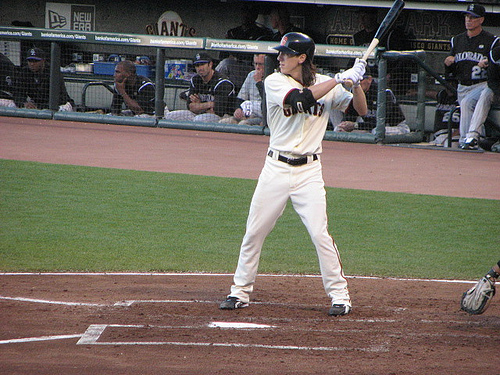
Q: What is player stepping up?
A: Dug-out.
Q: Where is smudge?
A: Home plate.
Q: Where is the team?
A: In dugout.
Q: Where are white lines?
A: In dirt.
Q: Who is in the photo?
A: A batter.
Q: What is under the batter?
A: Home plate.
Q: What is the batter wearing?
A: A Giants jersey.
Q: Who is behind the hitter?
A: Catcher.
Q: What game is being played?
A: Baseball.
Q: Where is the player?
A: On the field.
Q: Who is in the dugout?
A: Players.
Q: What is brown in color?
A: The dirt.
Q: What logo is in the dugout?
A: Giants logo.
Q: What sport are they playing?
A: Baseball.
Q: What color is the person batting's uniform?
A: White.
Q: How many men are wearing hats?
A: Five.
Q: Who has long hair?
A: The batter.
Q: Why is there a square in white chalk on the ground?
A: Shows home base.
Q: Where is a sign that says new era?
A: Back left.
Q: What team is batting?
A: Giants.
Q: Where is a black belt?
A: Around batters waist.